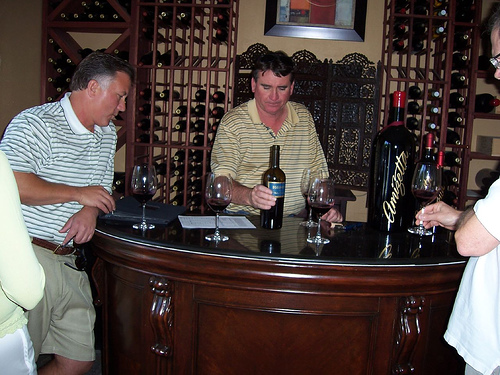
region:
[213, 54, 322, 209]
man wearing yellow shirt with stripes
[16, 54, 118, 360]
man leaning against the bar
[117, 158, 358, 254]
glasses of wine on the bar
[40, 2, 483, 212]
racks of wine on the wall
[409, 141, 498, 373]
man holding a wine glass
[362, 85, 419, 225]
oversized bottle of wine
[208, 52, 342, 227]
man holding a bottle of win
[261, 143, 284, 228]
tall bottle of wine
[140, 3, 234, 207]
a wooden wine rack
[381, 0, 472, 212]
a wooden wine rack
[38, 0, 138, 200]
a wooden wine rack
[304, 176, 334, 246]
a clear stemmed glass of wine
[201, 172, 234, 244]
a clear stemmed glass of wine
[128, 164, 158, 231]
a clear stemmed glass of wine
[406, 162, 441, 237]
a clear stemmed glass of wine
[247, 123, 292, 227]
a bottle on the counter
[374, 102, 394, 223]
a bottle on the counter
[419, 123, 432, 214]
a bottle on the counter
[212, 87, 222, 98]
a wine bottle on rack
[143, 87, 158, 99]
a wine bottle on rack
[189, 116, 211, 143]
a wine bottle on rack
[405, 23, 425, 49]
a wine bottle on rack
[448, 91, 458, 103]
a wine bottle on rack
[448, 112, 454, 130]
a wine bottle on rack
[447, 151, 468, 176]
a wine bottle on rack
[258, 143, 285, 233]
opened bottle of wine with a blue label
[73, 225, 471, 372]
dark wood bar front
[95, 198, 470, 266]
black wooden bar top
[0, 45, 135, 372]
man wearing a white striped shirt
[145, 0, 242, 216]
large wooden wine rack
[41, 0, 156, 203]
large wooden wine rack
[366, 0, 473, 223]
large wooden wine rack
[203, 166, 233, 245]
glass of red wine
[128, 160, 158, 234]
glass of red wine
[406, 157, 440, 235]
glass of red wine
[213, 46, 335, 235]
Man behind bar holding wine bottle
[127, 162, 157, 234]
Wine glass on the bar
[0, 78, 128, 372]
Man wearing striped shirt and khaki shorts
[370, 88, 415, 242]
Very large bottle of wine on the bar